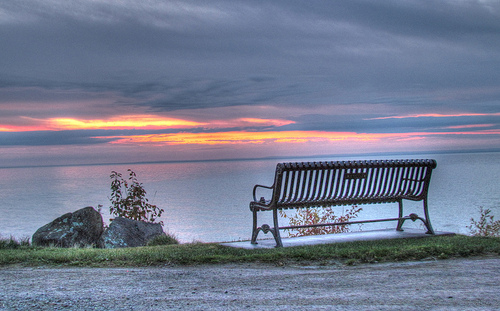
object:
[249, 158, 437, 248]
bench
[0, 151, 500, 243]
water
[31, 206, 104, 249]
rocks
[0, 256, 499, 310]
path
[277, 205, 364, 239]
shrub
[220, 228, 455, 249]
platform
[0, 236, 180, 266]
grass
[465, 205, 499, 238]
shrub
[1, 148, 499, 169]
horizon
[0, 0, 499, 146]
clouds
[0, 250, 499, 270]
edge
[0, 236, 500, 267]
grass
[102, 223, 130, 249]
lichen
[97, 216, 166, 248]
rock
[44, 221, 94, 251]
lichen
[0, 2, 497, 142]
sky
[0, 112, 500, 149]
sunset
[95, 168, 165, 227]
leaves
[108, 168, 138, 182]
tops